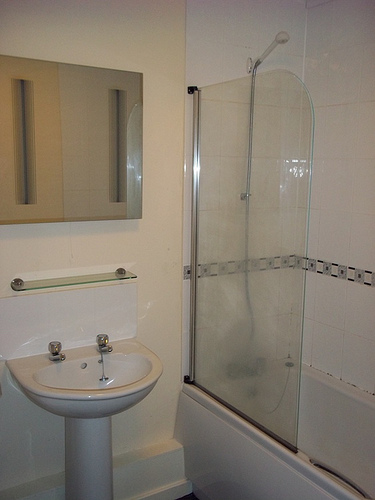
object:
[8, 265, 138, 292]
shelf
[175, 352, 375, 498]
bathtub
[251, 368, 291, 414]
chain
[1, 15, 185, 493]
wall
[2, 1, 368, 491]
bathroom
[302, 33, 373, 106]
tile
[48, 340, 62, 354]
knob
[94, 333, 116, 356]
faucet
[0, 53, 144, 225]
glass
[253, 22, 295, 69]
head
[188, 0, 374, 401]
wall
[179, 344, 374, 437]
mold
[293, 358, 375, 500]
base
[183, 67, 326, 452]
glass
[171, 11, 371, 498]
shower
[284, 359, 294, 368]
plug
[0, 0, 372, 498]
scene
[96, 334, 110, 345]
knob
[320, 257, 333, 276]
tile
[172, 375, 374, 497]
track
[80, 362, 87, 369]
hole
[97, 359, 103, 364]
hole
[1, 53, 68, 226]
door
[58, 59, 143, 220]
door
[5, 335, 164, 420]
sink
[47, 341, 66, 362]
faucet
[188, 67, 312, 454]
door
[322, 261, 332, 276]
design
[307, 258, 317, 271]
design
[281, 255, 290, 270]
design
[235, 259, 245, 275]
design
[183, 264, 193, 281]
design